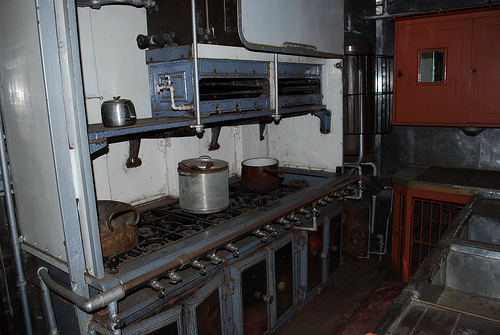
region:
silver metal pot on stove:
[172, 153, 243, 241]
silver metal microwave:
[194, 59, 256, 104]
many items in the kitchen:
[407, 21, 467, 113]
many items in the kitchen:
[112, 88, 142, 123]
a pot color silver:
[170, 146, 236, 225]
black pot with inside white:
[232, 145, 292, 204]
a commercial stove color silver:
[44, 147, 354, 329]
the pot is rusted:
[93, 184, 148, 271]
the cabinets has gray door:
[210, 225, 310, 330]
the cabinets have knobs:
[255, 271, 291, 306]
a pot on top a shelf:
[85, 83, 193, 150]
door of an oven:
[191, 52, 272, 121]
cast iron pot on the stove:
[89, 196, 140, 256]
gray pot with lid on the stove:
[178, 152, 228, 216]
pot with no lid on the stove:
[238, 157, 283, 192]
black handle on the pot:
[260, 169, 287, 183]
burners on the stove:
[95, 167, 305, 266]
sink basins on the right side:
[413, 191, 499, 315]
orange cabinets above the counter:
[386, 9, 498, 114]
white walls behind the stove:
[78, 8, 338, 215]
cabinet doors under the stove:
[130, 217, 346, 334]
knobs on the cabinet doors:
[260, 240, 350, 302]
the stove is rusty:
[137, 185, 244, 239]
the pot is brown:
[246, 156, 280, 190]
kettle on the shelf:
[97, 90, 144, 134]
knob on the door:
[258, 281, 276, 315]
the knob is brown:
[256, 286, 282, 307]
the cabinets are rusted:
[215, 265, 302, 330]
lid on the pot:
[186, 153, 231, 170]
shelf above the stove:
[90, 121, 211, 250]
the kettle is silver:
[94, 85, 136, 125]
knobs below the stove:
[150, 229, 244, 289]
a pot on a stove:
[169, 147, 235, 220]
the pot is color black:
[238, 151, 285, 200]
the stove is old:
[107, 167, 355, 327]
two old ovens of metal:
[148, 53, 331, 143]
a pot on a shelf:
[96, 91, 152, 147]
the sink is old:
[414, 201, 496, 321]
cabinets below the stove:
[182, 212, 345, 334]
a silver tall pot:
[174, 148, 234, 221]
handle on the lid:
[189, 150, 215, 165]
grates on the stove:
[116, 172, 304, 257]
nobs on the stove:
[126, 178, 376, 305]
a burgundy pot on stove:
[239, 149, 294, 196]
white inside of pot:
[239, 153, 276, 171]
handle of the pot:
[256, 162, 295, 186]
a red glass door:
[389, 177, 472, 287]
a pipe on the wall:
[226, 5, 353, 67]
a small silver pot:
[94, 85, 147, 133]